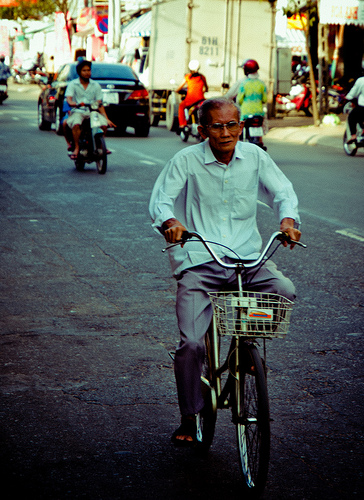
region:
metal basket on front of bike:
[208, 287, 290, 340]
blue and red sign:
[93, 12, 108, 32]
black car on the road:
[37, 62, 151, 136]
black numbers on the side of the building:
[198, 35, 220, 56]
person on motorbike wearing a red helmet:
[228, 58, 273, 151]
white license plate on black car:
[102, 92, 119, 103]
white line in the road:
[333, 225, 363, 245]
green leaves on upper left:
[0, 1, 68, 20]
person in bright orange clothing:
[179, 61, 208, 132]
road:
[2, 94, 361, 495]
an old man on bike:
[138, 87, 342, 475]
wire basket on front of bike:
[200, 280, 306, 347]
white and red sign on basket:
[246, 307, 281, 325]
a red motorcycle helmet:
[234, 56, 263, 80]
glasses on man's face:
[201, 115, 246, 138]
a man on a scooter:
[57, 62, 127, 177]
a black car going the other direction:
[39, 54, 153, 150]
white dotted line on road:
[124, 144, 363, 255]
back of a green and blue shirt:
[236, 78, 275, 128]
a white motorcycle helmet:
[185, 57, 202, 76]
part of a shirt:
[242, 214, 251, 227]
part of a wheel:
[245, 455, 254, 468]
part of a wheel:
[218, 390, 224, 405]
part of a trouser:
[184, 399, 206, 400]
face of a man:
[211, 103, 244, 156]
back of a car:
[116, 95, 141, 112]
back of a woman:
[250, 67, 257, 90]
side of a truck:
[183, 30, 191, 53]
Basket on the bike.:
[218, 291, 293, 333]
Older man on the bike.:
[150, 95, 298, 485]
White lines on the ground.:
[127, 146, 363, 275]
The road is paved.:
[4, 291, 147, 498]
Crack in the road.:
[61, 374, 173, 421]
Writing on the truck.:
[192, 26, 223, 71]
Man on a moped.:
[53, 57, 128, 172]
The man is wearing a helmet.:
[74, 57, 103, 87]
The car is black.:
[36, 60, 150, 132]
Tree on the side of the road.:
[295, 7, 342, 132]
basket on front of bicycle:
[204, 286, 297, 342]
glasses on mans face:
[204, 118, 240, 133]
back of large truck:
[150, 2, 278, 98]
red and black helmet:
[240, 59, 261, 74]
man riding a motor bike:
[62, 57, 112, 174]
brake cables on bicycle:
[160, 238, 296, 283]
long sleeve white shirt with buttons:
[147, 141, 310, 275]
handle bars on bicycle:
[165, 225, 308, 270]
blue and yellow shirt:
[232, 76, 276, 121]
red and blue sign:
[94, 13, 111, 36]